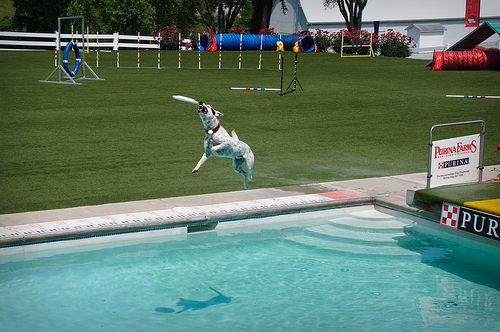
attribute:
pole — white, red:
[232, 31, 246, 68]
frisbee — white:
[172, 87, 205, 106]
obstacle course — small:
[11, 12, 498, 97]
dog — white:
[183, 93, 263, 195]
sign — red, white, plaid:
[434, 199, 459, 229]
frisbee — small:
[171, 92, 201, 106]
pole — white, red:
[92, 24, 182, 101]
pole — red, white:
[194, 31, 207, 71]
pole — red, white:
[249, 30, 266, 82]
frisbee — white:
[169, 90, 199, 105]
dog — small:
[180, 103, 246, 183]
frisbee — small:
[165, 86, 195, 111]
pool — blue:
[2, 190, 499, 330]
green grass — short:
[1, 51, 498, 213]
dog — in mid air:
[191, 101, 258, 190]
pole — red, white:
[131, 30, 145, 65]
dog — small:
[187, 98, 259, 189]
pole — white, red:
[444, 92, 499, 98]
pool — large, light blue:
[2, 207, 499, 329]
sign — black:
[425, 200, 484, 260]